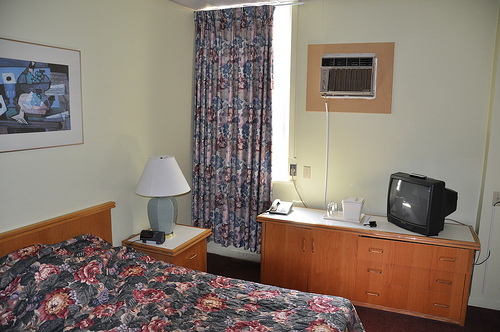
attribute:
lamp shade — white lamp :
[132, 152, 195, 198]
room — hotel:
[5, 5, 491, 324]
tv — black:
[384, 177, 486, 244]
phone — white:
[252, 185, 298, 225]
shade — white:
[132, 148, 194, 198]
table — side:
[120, 217, 212, 274]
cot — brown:
[0, 199, 121, 261]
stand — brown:
[112, 219, 212, 270]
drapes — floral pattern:
[194, 12, 269, 244]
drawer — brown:
[353, 235, 470, 277]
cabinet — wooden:
[265, 220, 312, 280]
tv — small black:
[386, 167, 467, 238]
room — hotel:
[9, 51, 490, 327]